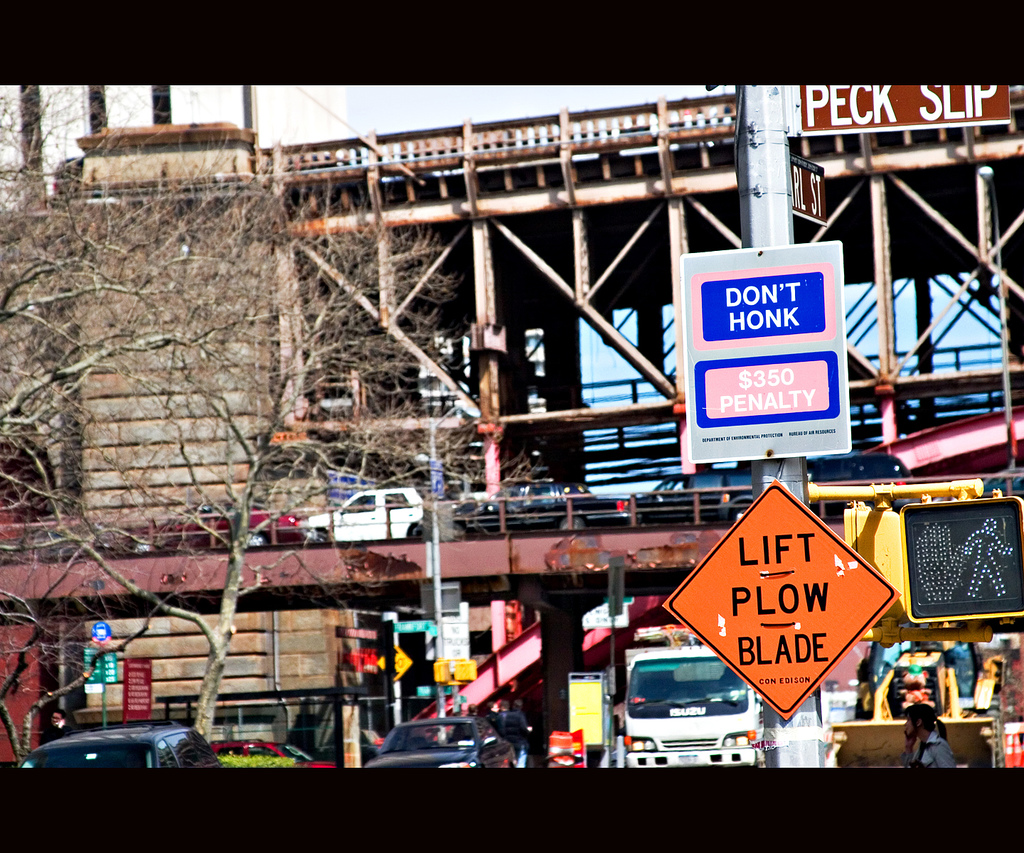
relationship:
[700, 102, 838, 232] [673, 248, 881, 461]
pole on poster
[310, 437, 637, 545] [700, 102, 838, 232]
cars near pole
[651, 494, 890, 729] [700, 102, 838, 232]
sign near pole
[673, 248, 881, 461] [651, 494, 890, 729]
poster near sign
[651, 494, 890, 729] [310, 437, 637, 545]
sign near cars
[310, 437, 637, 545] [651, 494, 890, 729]
cars near sign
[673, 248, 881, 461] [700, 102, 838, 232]
poster on pole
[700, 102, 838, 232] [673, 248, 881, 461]
pole holding poster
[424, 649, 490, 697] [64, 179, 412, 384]
light near tree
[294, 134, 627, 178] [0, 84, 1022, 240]
bridge has bridge